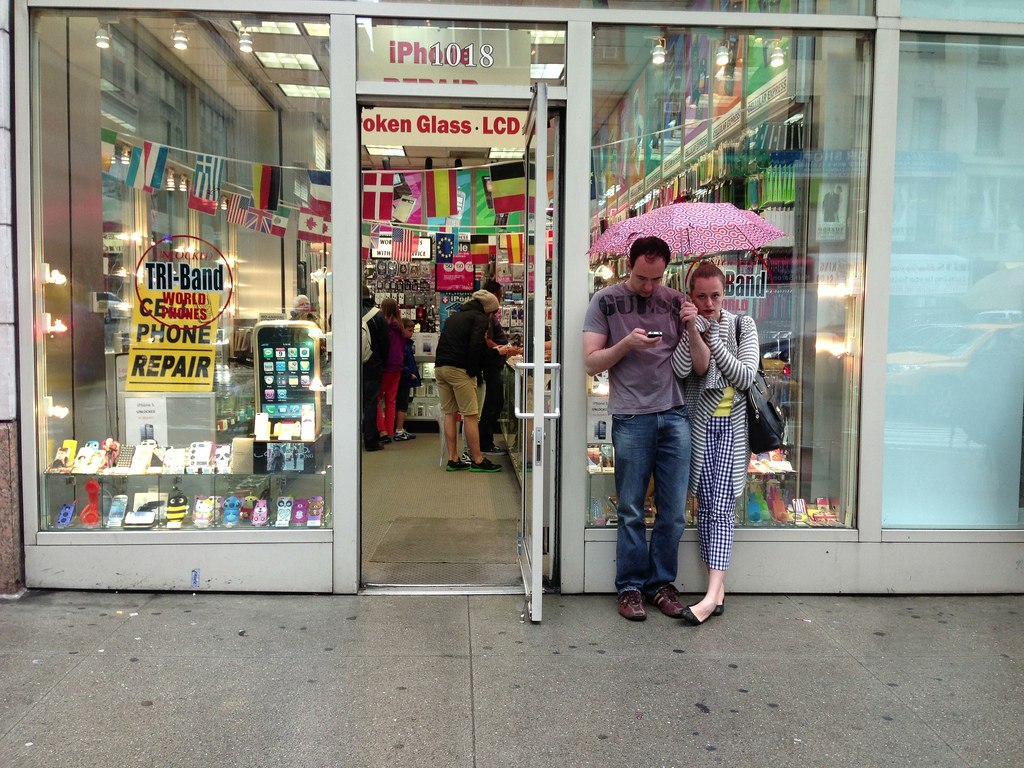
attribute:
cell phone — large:
[254, 321, 319, 448]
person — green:
[433, 289, 504, 479]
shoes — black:
[440, 456, 508, 475]